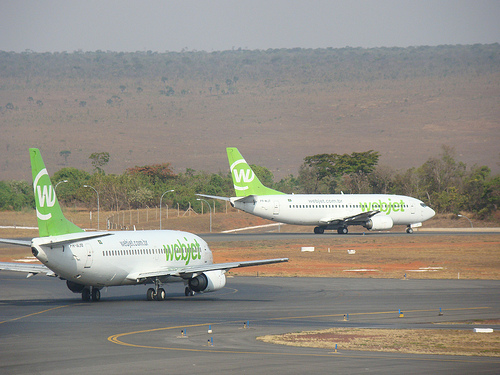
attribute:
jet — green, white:
[193, 145, 435, 235]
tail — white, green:
[27, 148, 80, 236]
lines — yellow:
[102, 304, 499, 371]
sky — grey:
[105, 7, 271, 39]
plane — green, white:
[193, 145, 438, 237]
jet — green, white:
[160, 129, 495, 281]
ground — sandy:
[355, 239, 492, 267]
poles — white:
[60, 174, 223, 230]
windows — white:
[281, 193, 423, 213]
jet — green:
[208, 156, 455, 251]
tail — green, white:
[223, 143, 285, 191]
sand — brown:
[3, 209, 494, 276]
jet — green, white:
[147, 62, 499, 274]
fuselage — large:
[200, 143, 434, 236]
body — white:
[7, 146, 287, 301]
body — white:
[195, 140, 439, 236]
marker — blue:
[235, 320, 253, 331]